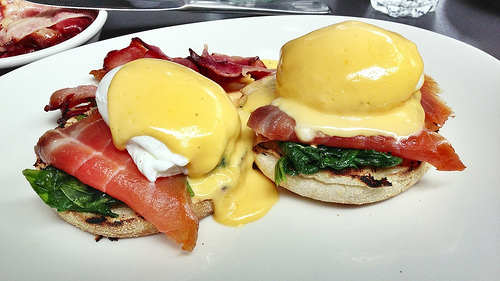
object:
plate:
[0, 14, 500, 281]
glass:
[369, 0, 439, 18]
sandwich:
[18, 57, 248, 253]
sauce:
[104, 19, 430, 226]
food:
[19, 16, 468, 253]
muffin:
[251, 142, 430, 207]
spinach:
[21, 162, 121, 217]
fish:
[244, 73, 471, 173]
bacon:
[89, 33, 277, 90]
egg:
[93, 56, 240, 183]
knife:
[18, 1, 334, 16]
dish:
[0, 8, 111, 69]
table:
[0, 0, 500, 76]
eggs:
[274, 19, 426, 115]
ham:
[32, 110, 247, 252]